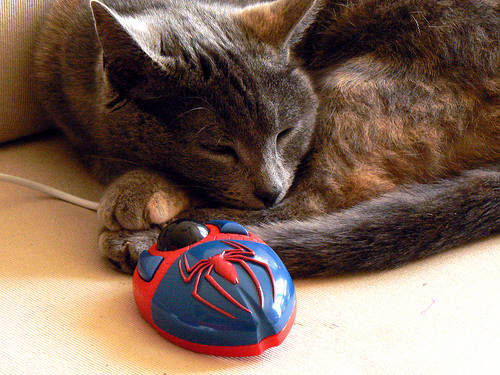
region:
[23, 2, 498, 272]
brown cat laying on furniture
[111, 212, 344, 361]
computer mouse laying on furniture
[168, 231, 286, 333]
red spider on computer mouse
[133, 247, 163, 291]
button on computer mouse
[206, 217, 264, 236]
Button on computer mouse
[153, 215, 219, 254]
Black ball on computer mouse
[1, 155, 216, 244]
White cord to computer mouse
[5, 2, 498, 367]
Tail on brown cat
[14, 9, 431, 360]
Brown cat and computer mouse laying on brown furniture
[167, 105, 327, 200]
Brown cat's eyes shut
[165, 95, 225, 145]
the cats grey eye brows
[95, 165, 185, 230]
the cats brown paw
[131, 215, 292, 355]
a plastic spider man toy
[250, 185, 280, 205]
the cat has a black nose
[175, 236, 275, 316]
a red spider image on the toy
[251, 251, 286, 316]
a reflection of light on the plastic toy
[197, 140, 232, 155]
the cats closed eye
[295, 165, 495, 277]
the cats long grey tail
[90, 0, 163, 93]
the cats pointy ear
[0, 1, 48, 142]
a beige sofa cushion back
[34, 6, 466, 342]
cat is laying down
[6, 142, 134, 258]
white cord under the cat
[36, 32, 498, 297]
the cat is brown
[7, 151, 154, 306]
the cord is white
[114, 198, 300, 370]
spiderman logo toy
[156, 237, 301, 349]
toy is red and blue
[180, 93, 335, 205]
cat has it's eyes closed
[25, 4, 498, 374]
cat is laying by the toy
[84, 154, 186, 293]
cat has its paws together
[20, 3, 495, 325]
the cat is taking a nap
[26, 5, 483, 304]
grey cat on couch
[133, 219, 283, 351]
spider man computer mouse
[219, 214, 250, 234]
button on computer mouse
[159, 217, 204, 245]
scroll ball on computer mouse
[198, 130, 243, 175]
eye of grey cat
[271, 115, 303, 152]
eye of grey cat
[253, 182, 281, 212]
nose of grey cat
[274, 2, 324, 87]
ear of grey cat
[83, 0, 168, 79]
ear of grey cat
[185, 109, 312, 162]
Sleepy cat eyes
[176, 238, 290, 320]
A red spider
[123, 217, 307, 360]
A red and blue computer mouse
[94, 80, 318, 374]
A computer mouse in front of a cat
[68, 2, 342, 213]
A gray cat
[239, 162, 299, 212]
The nose of a cat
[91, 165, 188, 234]
A cat paw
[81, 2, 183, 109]
A cat ear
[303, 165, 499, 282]
A gray cat tail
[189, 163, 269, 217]
A cat's whisker pad